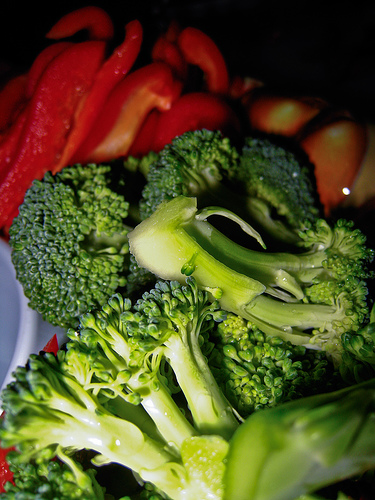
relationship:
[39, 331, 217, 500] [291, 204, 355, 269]
light on broccoli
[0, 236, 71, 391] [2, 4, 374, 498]
plate under vegetables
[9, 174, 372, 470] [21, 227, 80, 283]
broccoli with bulbs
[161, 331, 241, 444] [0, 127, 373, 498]
stem of broccoli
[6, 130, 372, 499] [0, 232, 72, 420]
vetables on a plate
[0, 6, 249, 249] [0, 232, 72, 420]
vetables on a plate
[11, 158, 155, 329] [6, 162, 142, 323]
piece of brocolli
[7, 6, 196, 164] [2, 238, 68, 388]
pepper on a plate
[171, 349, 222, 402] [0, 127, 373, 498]
stem of broccoli